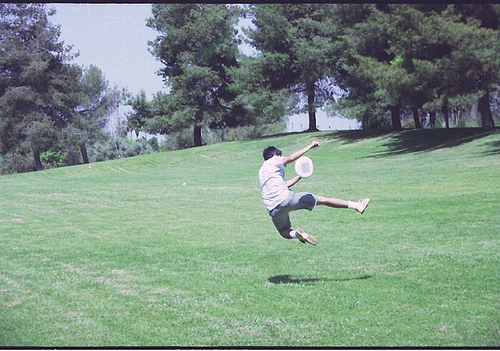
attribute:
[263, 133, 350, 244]
boy — jumping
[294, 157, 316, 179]
frisbee — white, round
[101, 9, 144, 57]
sky — blue